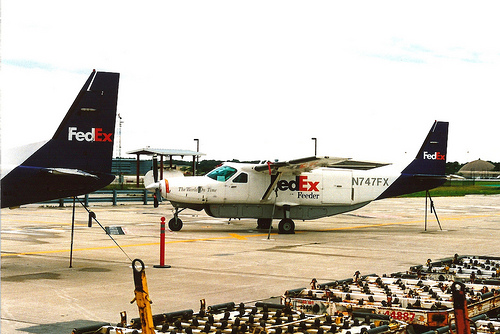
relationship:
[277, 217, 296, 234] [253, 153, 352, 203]
wheel mounted under wing